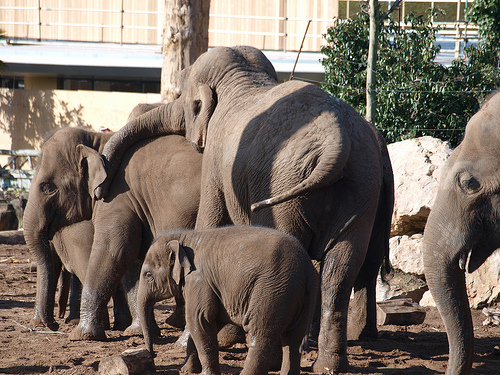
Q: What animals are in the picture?
A: Elephants.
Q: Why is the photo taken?
A: To capture the elephants.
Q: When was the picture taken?
A: Daytime.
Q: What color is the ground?
A: Brown.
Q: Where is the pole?
A: In front of the elephants.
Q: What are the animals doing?
A: Walking together.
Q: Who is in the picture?
A: No one.